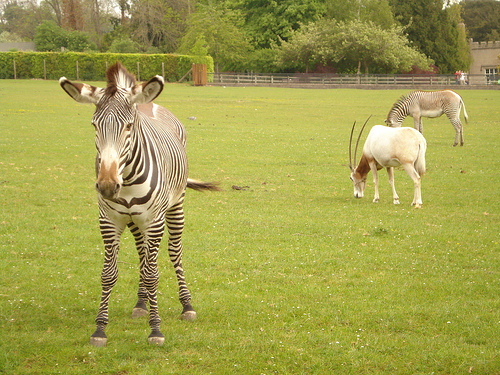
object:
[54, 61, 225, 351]
zebra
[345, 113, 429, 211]
animal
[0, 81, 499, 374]
grass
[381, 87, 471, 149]
zebra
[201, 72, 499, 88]
fence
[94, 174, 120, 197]
snout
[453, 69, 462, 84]
person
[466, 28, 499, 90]
building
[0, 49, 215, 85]
hedge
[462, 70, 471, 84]
person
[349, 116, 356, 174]
horn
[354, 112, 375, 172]
horn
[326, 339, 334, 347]
flower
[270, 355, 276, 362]
flower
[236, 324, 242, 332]
flower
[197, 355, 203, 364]
flower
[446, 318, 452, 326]
flower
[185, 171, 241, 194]
tail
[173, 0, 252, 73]
tree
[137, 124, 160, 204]
stripe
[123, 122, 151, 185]
stripe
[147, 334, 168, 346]
dirt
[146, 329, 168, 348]
hoofs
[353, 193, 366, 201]
grazing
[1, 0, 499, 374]
wooded area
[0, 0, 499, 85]
background